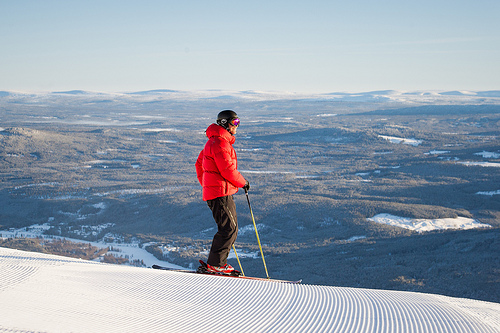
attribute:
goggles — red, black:
[227, 116, 239, 127]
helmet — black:
[217, 107, 252, 149]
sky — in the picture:
[8, 11, 480, 91]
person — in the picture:
[191, 95, 258, 293]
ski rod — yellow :
[246, 179, 289, 294]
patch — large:
[364, 211, 491, 236]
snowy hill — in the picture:
[5, 241, 499, 332]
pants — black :
[205, 194, 237, 266]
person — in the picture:
[188, 107, 253, 271]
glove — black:
[240, 175, 260, 196]